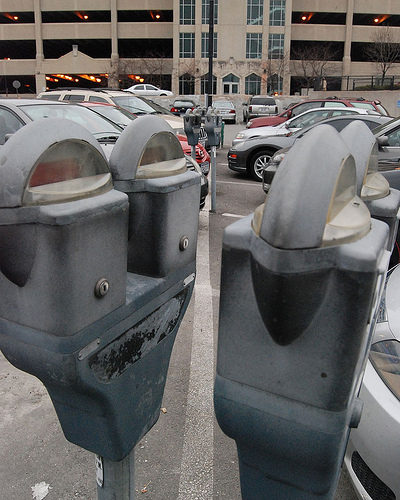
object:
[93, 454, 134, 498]
pole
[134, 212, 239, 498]
road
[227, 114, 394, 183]
car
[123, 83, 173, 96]
car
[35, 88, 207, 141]
car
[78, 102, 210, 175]
car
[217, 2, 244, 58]
wall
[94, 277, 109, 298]
hole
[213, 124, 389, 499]
littered tarmac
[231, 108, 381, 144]
car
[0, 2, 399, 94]
building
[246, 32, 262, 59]
window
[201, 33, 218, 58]
window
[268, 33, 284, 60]
window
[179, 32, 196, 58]
window